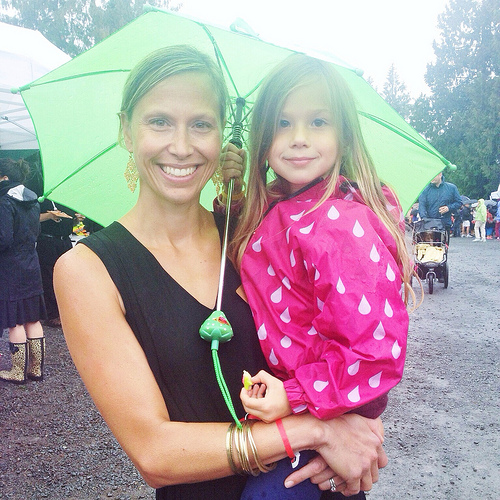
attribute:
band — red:
[269, 413, 301, 460]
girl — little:
[218, 39, 423, 474]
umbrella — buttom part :
[22, 3, 476, 360]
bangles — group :
[223, 417, 261, 484]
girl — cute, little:
[229, 49, 432, 498]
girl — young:
[241, 40, 427, 498]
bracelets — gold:
[222, 418, 271, 483]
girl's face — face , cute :
[265, 84, 340, 185]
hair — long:
[244, 67, 374, 212]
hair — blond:
[221, 52, 423, 274]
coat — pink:
[205, 167, 407, 425]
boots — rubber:
[1, 334, 51, 387]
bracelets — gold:
[221, 422, 272, 482]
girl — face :
[251, 62, 366, 193]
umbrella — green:
[32, 6, 439, 251]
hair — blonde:
[225, 55, 423, 312]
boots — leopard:
[7, 333, 52, 392]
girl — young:
[235, 59, 396, 499]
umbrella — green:
[24, 15, 449, 264]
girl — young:
[232, 44, 415, 498]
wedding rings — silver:
[324, 477, 338, 489]